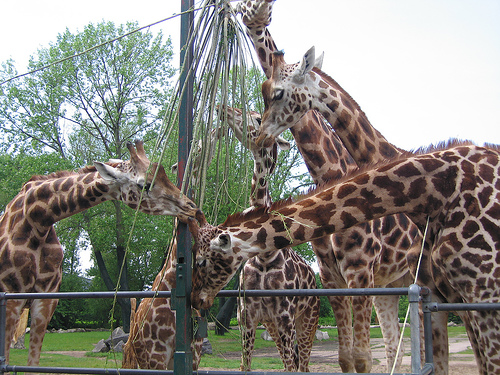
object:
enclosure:
[3, 277, 498, 374]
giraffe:
[120, 122, 230, 369]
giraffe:
[191, 136, 498, 371]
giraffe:
[255, 48, 498, 373]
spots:
[434, 211, 473, 227]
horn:
[127, 141, 137, 163]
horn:
[135, 138, 144, 156]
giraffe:
[6, 148, 201, 353]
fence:
[0, 282, 460, 373]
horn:
[263, 46, 287, 71]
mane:
[21, 160, 118, 181]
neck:
[22, 160, 123, 226]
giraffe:
[205, 99, 327, 373]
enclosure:
[1, 2, 498, 369]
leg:
[0, 292, 29, 369]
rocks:
[88, 324, 130, 356]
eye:
[263, 89, 288, 108]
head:
[239, 45, 347, 155]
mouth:
[213, 107, 318, 159]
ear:
[92, 159, 128, 186]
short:
[125, 139, 149, 165]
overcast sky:
[329, 11, 490, 91]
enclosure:
[1, 288, 499, 372]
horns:
[121, 143, 141, 165]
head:
[117, 153, 206, 227]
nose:
[180, 197, 200, 213]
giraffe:
[246, 37, 498, 327]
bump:
[146, 159, 167, 180]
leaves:
[40, 33, 78, 71]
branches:
[51, 53, 112, 145]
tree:
[19, 13, 160, 318]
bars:
[6, 280, 402, 367]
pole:
[400, 286, 429, 373]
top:
[105, 321, 130, 336]